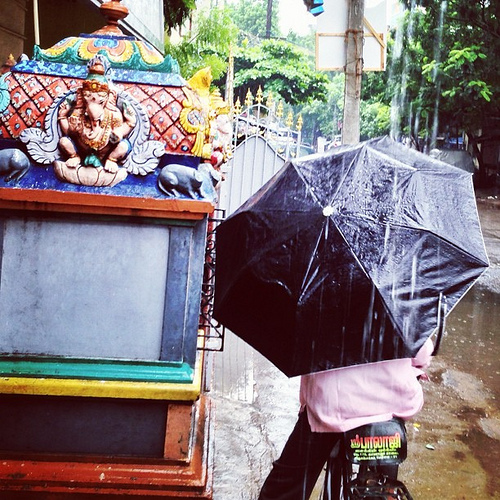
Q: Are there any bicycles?
A: Yes, there is a bicycle.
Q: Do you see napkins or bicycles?
A: Yes, there is a bicycle.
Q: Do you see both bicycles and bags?
A: No, there is a bicycle but no bags.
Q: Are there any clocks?
A: No, there are no clocks.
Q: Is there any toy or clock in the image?
A: No, there are no clocks or toys.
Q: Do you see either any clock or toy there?
A: No, there are no clocks or toys.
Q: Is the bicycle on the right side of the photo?
A: Yes, the bicycle is on the right of the image.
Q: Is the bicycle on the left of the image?
A: No, the bicycle is on the right of the image.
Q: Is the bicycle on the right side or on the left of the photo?
A: The bicycle is on the right of the image.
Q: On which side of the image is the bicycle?
A: The bicycle is on the right of the image.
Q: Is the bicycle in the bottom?
A: Yes, the bicycle is in the bottom of the image.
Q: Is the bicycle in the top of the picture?
A: No, the bicycle is in the bottom of the image.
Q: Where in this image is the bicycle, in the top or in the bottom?
A: The bicycle is in the bottom of the image.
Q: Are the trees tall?
A: Yes, the trees are tall.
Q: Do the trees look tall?
A: Yes, the trees are tall.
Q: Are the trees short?
A: No, the trees are tall.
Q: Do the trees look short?
A: No, the trees are tall.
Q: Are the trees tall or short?
A: The trees are tall.